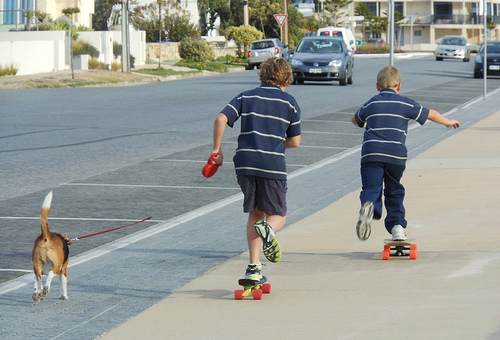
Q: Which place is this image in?
A: It is at the street.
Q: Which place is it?
A: It is a street.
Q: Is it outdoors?
A: Yes, it is outdoors.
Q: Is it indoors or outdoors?
A: It is outdoors.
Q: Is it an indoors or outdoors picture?
A: It is outdoors.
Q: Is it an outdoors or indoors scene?
A: It is outdoors.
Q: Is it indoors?
A: No, it is outdoors.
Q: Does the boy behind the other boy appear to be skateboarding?
A: Yes, the boy is skateboarding.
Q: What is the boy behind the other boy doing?
A: The boy is skateboarding.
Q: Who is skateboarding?
A: The boy is skateboarding.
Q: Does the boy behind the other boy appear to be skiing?
A: No, the boy is skateboarding.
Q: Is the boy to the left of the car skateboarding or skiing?
A: The boy is skateboarding.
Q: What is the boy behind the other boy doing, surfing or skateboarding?
A: The boy is skateboarding.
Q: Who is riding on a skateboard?
A: The boy is riding on a skateboard.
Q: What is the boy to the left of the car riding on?
A: The boy is riding on a skateboard.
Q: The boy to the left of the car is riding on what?
A: The boy is riding on a skateboard.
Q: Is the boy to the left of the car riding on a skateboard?
A: Yes, the boy is riding on a skateboard.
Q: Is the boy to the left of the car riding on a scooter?
A: No, the boy is riding on a skateboard.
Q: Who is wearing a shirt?
A: The boy is wearing a shirt.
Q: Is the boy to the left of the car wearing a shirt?
A: Yes, the boy is wearing a shirt.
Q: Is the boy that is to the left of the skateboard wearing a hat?
A: No, the boy is wearing a shirt.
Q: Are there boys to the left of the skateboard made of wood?
A: Yes, there is a boy to the left of the skateboard.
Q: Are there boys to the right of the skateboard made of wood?
A: No, the boy is to the left of the skateboard.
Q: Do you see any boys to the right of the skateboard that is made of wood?
A: No, the boy is to the left of the skateboard.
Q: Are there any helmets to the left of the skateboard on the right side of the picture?
A: No, there is a boy to the left of the skateboard.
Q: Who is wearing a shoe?
A: The boy is wearing a shoe.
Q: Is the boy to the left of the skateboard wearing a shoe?
A: Yes, the boy is wearing a shoe.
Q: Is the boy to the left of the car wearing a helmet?
A: No, the boy is wearing a shoe.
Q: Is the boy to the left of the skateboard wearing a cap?
A: No, the boy is wearing a shoe.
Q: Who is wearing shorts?
A: The boy is wearing shorts.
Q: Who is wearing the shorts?
A: The boy is wearing shorts.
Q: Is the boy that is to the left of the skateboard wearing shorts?
A: Yes, the boy is wearing shorts.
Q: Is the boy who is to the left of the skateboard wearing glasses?
A: No, the boy is wearing shorts.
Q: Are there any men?
A: No, there are no men.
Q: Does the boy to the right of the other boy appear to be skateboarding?
A: Yes, the boy is skateboarding.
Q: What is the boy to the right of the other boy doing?
A: The boy is skateboarding.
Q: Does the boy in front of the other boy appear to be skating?
A: No, the boy is skateboarding.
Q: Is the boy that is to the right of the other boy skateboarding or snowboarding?
A: The boy is skateboarding.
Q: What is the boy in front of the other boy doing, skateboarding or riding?
A: The boy is skateboarding.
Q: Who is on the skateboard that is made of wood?
A: The boy is on the skateboard.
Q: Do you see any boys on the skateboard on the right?
A: Yes, there is a boy on the skateboard.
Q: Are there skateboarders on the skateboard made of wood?
A: No, there is a boy on the skateboard.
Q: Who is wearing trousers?
A: The boy is wearing trousers.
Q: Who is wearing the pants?
A: The boy is wearing trousers.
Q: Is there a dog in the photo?
A: Yes, there is a dog.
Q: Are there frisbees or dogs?
A: Yes, there is a dog.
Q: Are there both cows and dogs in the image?
A: No, there is a dog but no cows.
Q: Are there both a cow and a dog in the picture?
A: No, there is a dog but no cows.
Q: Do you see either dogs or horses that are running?
A: Yes, the dog is running.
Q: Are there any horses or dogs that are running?
A: Yes, the dog is running.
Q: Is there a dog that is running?
A: Yes, there is a dog that is running.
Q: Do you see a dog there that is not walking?
A: Yes, there is a dog that is running .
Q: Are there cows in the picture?
A: No, there are no cows.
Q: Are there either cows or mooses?
A: No, there are no cows or mooses.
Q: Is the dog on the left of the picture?
A: Yes, the dog is on the left of the image.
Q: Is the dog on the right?
A: No, the dog is on the left of the image.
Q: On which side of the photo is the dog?
A: The dog is on the left of the image.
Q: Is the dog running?
A: Yes, the dog is running.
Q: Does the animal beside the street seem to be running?
A: Yes, the dog is running.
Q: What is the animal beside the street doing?
A: The dog is running.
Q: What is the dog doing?
A: The dog is running.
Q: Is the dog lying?
A: No, the dog is running.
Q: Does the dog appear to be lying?
A: No, the dog is running.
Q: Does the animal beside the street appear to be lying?
A: No, the dog is running.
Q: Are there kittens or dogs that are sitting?
A: No, there is a dog but it is running.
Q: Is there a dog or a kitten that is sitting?
A: No, there is a dog but it is running.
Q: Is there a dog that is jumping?
A: No, there is a dog but it is running.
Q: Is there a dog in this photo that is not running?
A: No, there is a dog but it is running.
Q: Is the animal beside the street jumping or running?
A: The dog is running.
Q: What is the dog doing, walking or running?
A: The dog is running.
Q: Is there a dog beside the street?
A: Yes, there is a dog beside the street.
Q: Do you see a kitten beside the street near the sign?
A: No, there is a dog beside the street.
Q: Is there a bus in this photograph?
A: No, there are no buses.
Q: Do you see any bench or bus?
A: No, there are no buses or benches.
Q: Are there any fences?
A: No, there are no fences.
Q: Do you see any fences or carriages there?
A: No, there are no fences or carriages.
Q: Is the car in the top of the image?
A: Yes, the car is in the top of the image.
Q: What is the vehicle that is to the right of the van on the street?
A: The vehicle is a car.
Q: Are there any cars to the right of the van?
A: Yes, there is a car to the right of the van.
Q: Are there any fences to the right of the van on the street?
A: No, there is a car to the right of the van.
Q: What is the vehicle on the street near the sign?
A: The vehicle is a car.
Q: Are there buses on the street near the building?
A: No, there is a car on the street.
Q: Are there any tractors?
A: No, there are no tractors.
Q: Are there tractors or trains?
A: No, there are no tractors or trains.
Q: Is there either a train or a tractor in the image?
A: No, there are no tractors or trains.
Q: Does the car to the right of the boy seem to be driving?
A: Yes, the car is driving.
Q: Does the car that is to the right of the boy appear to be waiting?
A: No, the car is driving.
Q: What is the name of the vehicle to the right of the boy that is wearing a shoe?
A: The vehicle is a car.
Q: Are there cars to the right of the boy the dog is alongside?
A: Yes, there is a car to the right of the boy.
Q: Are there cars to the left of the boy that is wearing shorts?
A: No, the car is to the right of the boy.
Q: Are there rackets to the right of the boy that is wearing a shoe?
A: No, there is a car to the right of the boy.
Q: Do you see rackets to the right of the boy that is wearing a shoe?
A: No, there is a car to the right of the boy.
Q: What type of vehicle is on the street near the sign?
A: The vehicle is a car.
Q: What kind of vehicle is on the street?
A: The vehicle is a car.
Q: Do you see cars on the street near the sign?
A: Yes, there is a car on the street.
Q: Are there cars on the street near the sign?
A: Yes, there is a car on the street.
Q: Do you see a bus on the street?
A: No, there is a car on the street.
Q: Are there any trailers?
A: No, there are no trailers.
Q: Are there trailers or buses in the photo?
A: No, there are no trailers or buses.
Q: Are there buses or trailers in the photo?
A: No, there are no trailers or buses.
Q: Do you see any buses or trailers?
A: No, there are no trailers or buses.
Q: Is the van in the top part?
A: Yes, the van is in the top of the image.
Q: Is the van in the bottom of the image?
A: No, the van is in the top of the image.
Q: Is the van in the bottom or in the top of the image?
A: The van is in the top of the image.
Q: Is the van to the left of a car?
A: Yes, the van is to the left of a car.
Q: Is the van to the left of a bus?
A: No, the van is to the left of a car.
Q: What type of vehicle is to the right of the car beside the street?
A: The vehicle is a van.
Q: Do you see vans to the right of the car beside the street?
A: Yes, there is a van to the right of the car.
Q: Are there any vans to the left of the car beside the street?
A: No, the van is to the right of the car.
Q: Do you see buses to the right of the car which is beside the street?
A: No, there is a van to the right of the car.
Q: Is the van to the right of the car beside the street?
A: Yes, the van is to the right of the car.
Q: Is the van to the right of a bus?
A: No, the van is to the right of the car.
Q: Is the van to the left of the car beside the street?
A: No, the van is to the right of the car.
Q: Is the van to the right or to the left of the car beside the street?
A: The van is to the right of the car.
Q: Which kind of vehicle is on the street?
A: The vehicle is a van.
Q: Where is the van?
A: The van is on the street.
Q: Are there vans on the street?
A: Yes, there is a van on the street.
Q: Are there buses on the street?
A: No, there is a van on the street.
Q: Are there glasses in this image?
A: No, there are no glasses.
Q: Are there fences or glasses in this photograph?
A: No, there are no glasses or fences.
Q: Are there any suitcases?
A: No, there are no suitcases.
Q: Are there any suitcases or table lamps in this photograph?
A: No, there are no suitcases or table lamps.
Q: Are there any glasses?
A: No, there are no glasses.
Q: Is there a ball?
A: No, there are no balls.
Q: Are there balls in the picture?
A: No, there are no balls.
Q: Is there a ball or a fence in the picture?
A: No, there are no balls or fences.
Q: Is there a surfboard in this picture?
A: No, there are no surfboards.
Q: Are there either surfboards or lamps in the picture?
A: No, there are no surfboards or lamps.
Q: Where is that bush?
A: The bush is on the sidewalk.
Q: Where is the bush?
A: The bush is on the sidewalk.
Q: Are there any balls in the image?
A: No, there are no balls.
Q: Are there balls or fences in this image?
A: No, there are no balls or fences.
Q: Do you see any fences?
A: No, there are no fences.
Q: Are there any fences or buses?
A: No, there are no fences or buses.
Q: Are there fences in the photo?
A: No, there are no fences.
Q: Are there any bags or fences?
A: No, there are no fences or bags.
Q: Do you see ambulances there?
A: No, there are no ambulances.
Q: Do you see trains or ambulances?
A: No, there are no ambulances or trains.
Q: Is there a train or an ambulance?
A: No, there are no ambulances or trains.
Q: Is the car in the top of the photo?
A: Yes, the car is in the top of the image.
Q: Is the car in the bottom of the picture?
A: No, the car is in the top of the image.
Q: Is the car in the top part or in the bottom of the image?
A: The car is in the top of the image.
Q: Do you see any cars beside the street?
A: Yes, there is a car beside the street.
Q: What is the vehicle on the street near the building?
A: The vehicle is a car.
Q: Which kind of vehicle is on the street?
A: The vehicle is a car.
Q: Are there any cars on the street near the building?
A: Yes, there is a car on the street.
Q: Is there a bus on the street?
A: No, there is a car on the street.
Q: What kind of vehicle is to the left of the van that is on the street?
A: The vehicle is a car.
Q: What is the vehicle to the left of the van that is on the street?
A: The vehicle is a car.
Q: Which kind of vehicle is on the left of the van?
A: The vehicle is a car.